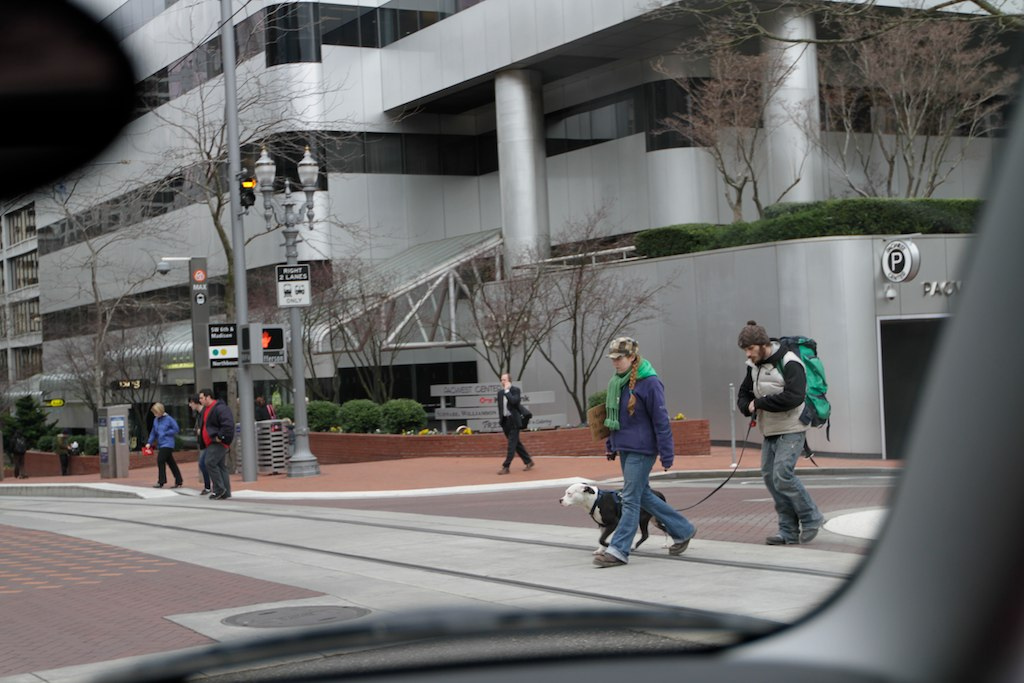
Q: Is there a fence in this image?
A: No, there are no fences.